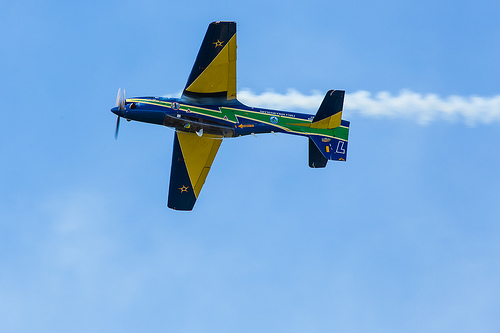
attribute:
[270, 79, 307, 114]
stripe — green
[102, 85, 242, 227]
nose — blue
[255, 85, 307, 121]
number — Blue 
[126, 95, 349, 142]
stripe — green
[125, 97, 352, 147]
stripe — green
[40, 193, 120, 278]
cloud — white 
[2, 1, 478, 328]
sky — blue , bright 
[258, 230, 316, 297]
cloud — white 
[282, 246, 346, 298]
cloud — white 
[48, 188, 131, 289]
cloud — white 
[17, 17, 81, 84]
cloud — white 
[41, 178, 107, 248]
cloud — white 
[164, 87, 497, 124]
smoke — white 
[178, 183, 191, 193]
star — small 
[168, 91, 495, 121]
contrail — white 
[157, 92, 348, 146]
stripe — green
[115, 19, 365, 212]
paint — black, yellow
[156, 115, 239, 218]
wing — yellow, black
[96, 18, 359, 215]
airplane — multi-coloured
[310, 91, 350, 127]
wing — blue, yellow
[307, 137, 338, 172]
wing — blue, yellow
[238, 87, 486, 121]
cloud — white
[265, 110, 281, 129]
logo — blue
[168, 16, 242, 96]
wing — blue, yellow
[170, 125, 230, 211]
wing — blue, yellow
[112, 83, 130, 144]
propellor — white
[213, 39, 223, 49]
star — yellow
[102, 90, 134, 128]
nose — blue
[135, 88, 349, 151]
stripe — green